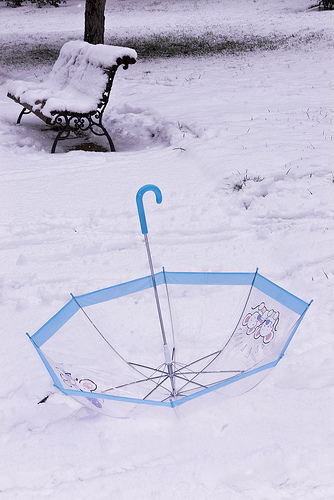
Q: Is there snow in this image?
A: Yes, there is snow.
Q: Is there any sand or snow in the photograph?
A: Yes, there is snow.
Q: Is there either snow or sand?
A: Yes, there is snow.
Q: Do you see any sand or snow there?
A: Yes, there is snow.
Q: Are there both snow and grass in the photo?
A: Yes, there are both snow and grass.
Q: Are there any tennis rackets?
A: No, there are no tennis rackets.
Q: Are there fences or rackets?
A: No, there are no rackets or fences.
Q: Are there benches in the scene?
A: Yes, there is a bench.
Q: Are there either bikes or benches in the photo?
A: Yes, there is a bench.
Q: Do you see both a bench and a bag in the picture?
A: No, there is a bench but no bags.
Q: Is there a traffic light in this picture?
A: No, there are no traffic lights.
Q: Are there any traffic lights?
A: No, there are no traffic lights.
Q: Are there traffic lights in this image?
A: No, there are no traffic lights.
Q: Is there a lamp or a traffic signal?
A: No, there are no traffic lights or lamps.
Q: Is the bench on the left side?
A: Yes, the bench is on the left of the image.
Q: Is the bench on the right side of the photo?
A: No, the bench is on the left of the image.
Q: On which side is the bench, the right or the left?
A: The bench is on the left of the image.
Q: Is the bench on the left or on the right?
A: The bench is on the left of the image.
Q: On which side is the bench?
A: The bench is on the left of the image.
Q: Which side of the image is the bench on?
A: The bench is on the left of the image.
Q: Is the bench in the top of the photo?
A: Yes, the bench is in the top of the image.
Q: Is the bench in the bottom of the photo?
A: No, the bench is in the top of the image.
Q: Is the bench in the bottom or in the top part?
A: The bench is in the top of the image.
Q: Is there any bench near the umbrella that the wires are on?
A: Yes, there is a bench near the umbrella.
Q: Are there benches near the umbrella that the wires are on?
A: Yes, there is a bench near the umbrella.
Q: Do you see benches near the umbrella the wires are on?
A: Yes, there is a bench near the umbrella.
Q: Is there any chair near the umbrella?
A: No, there is a bench near the umbrella.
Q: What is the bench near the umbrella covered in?
A: The bench is covered in snow.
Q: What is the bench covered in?
A: The bench is covered in snow.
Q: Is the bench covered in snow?
A: Yes, the bench is covered in snow.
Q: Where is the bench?
A: The bench is in the snow.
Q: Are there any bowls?
A: No, there are no bowls.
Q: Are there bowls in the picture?
A: No, there are no bowls.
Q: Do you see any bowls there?
A: No, there are no bowls.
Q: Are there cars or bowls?
A: No, there are no bowls or cars.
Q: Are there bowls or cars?
A: No, there are no bowls or cars.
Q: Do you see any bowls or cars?
A: No, there are no bowls or cars.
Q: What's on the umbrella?
A: The wires are on the umbrella.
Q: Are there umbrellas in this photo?
A: Yes, there is an umbrella.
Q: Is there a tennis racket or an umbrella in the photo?
A: Yes, there is an umbrella.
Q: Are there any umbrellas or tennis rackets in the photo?
A: Yes, there is an umbrella.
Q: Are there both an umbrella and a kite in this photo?
A: No, there is an umbrella but no kites.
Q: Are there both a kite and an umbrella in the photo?
A: No, there is an umbrella but no kites.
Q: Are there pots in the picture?
A: No, there are no pots.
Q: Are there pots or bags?
A: No, there are no pots or bags.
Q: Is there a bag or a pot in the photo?
A: No, there are no pots or bags.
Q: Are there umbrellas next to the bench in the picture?
A: Yes, there is an umbrella next to the bench.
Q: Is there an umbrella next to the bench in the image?
A: Yes, there is an umbrella next to the bench.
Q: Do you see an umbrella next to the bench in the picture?
A: Yes, there is an umbrella next to the bench.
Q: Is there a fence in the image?
A: No, there are no fences.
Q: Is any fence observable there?
A: No, there are no fences.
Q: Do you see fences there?
A: No, there are no fences.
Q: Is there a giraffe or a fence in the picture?
A: No, there are no fences or giraffes.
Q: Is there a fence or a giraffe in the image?
A: No, there are no fences or giraffes.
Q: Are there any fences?
A: No, there are no fences.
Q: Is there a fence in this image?
A: No, there are no fences.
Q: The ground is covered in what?
A: The ground is covered in snow.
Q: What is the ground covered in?
A: The ground is covered in snow.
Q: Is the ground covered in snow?
A: Yes, the ground is covered in snow.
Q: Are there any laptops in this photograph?
A: No, there are no laptops.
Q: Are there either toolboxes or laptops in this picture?
A: No, there are no laptops or toolboxes.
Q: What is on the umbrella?
A: The wires are on the umbrella.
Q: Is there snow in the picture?
A: Yes, there is snow.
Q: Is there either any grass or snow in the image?
A: Yes, there is snow.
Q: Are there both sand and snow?
A: No, there is snow but no sand.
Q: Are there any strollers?
A: No, there are no strollers.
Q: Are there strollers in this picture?
A: No, there are no strollers.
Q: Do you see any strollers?
A: No, there are no strollers.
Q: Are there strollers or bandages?
A: No, there are no strollers or bandages.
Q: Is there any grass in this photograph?
A: Yes, there is grass.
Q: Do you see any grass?
A: Yes, there is grass.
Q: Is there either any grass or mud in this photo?
A: Yes, there is grass.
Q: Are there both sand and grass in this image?
A: No, there is grass but no sand.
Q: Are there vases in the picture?
A: No, there are no vases.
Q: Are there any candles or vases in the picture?
A: No, there are no vases or candles.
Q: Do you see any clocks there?
A: No, there are no clocks.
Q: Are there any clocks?
A: No, there are no clocks.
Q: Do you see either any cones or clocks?
A: No, there are no clocks or cones.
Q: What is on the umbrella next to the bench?
A: The wires are on the umbrella.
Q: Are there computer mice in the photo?
A: Yes, there is a computer mouse.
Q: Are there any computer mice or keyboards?
A: Yes, there is a computer mouse.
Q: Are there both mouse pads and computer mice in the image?
A: No, there is a computer mouse but no mouse pads.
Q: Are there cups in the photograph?
A: No, there are no cups.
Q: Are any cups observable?
A: No, there are no cups.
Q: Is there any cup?
A: No, there are no cups.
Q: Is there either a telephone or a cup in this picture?
A: No, there are no cups or phones.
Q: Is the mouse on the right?
A: Yes, the mouse is on the right of the image.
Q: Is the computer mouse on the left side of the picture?
A: No, the computer mouse is on the right of the image.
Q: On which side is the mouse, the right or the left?
A: The mouse is on the right of the image.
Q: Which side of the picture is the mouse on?
A: The mouse is on the right of the image.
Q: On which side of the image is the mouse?
A: The mouse is on the right of the image.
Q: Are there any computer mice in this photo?
A: Yes, there is a computer mouse.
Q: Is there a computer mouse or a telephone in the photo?
A: Yes, there is a computer mouse.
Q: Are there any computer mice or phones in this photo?
A: Yes, there is a computer mouse.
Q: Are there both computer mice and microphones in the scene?
A: No, there is a computer mouse but no microphones.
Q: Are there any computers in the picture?
A: No, there are no computers.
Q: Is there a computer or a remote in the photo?
A: No, there are no computers or remote controls.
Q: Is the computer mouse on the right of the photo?
A: Yes, the computer mouse is on the right of the image.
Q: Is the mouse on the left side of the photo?
A: No, the mouse is on the right of the image.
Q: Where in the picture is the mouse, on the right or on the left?
A: The mouse is on the right of the image.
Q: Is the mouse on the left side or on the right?
A: The mouse is on the right of the image.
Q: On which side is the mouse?
A: The mouse is on the right of the image.